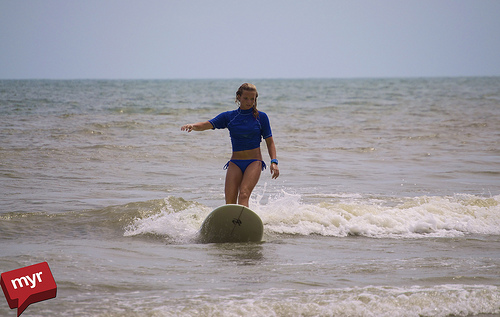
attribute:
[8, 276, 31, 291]
letter — m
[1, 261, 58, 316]
box — myr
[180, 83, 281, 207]
surfer — tan, woman, surfing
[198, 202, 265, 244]
surfboard — white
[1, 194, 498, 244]
wave — settled, mild, white, gray, small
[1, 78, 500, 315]
water — ripply, wavy, bluer, even-tempered, calm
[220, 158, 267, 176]
bikini bottom — blue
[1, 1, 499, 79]
sky — clear, blue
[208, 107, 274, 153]
shirt — blue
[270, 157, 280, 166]
bracelet — blue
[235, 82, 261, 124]
hair — wet, blond